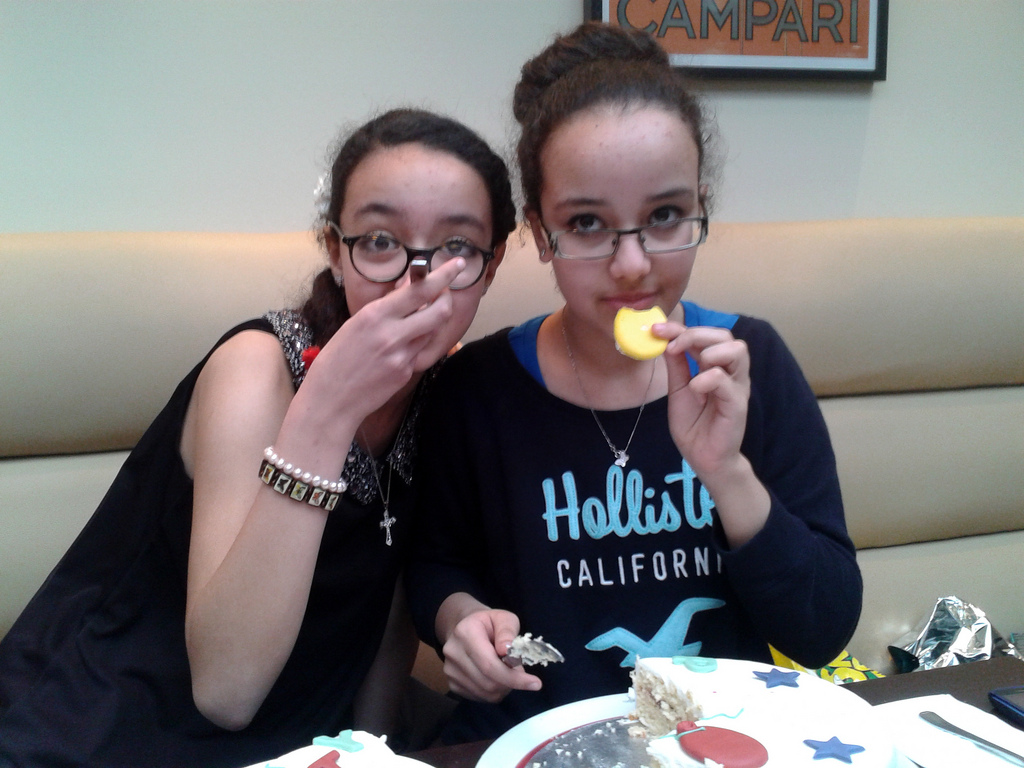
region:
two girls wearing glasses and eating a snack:
[0, 17, 868, 767]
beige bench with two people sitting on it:
[4, 19, 1023, 766]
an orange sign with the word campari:
[578, 1, 892, 79]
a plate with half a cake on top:
[460, 652, 890, 767]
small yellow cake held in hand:
[612, 306, 758, 474]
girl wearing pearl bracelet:
[4, 104, 521, 767]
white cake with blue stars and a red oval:
[622, 654, 891, 766]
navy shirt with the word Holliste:
[397, 311, 863, 745]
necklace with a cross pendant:
[355, 421, 401, 545]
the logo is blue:
[566, 579, 740, 687]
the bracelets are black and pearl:
[248, 424, 359, 529]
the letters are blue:
[529, 450, 732, 572]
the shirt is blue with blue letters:
[386, 330, 874, 703]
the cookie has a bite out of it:
[601, 292, 690, 365]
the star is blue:
[741, 632, 814, 709]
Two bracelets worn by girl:
[252, 437, 366, 524]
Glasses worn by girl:
[520, 182, 721, 263]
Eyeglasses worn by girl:
[337, 225, 505, 301]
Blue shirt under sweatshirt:
[484, 296, 748, 421]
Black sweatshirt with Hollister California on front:
[362, 286, 872, 758]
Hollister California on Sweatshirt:
[525, 444, 737, 596]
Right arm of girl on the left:
[171, 248, 470, 723]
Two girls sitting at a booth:
[0, 17, 890, 764]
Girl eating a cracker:
[400, 9, 866, 709]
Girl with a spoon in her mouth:
[8, 101, 520, 763]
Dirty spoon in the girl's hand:
[439, 581, 564, 714]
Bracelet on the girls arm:
[259, 442, 343, 519]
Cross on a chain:
[375, 493, 398, 554]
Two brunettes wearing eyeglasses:
[0, 23, 863, 764]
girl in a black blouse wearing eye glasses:
[0, 111, 514, 745]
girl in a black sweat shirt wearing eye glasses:
[517, 31, 860, 668]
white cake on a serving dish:
[477, 658, 908, 766]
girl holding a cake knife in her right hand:
[366, 401, 645, 765]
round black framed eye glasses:
[321, 217, 506, 297]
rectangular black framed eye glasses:
[520, 195, 716, 268]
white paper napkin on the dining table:
[875, 689, 1022, 763]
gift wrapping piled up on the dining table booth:
[815, 593, 1022, 683]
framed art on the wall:
[688, 0, 892, 93]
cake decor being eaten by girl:
[605, 295, 670, 368]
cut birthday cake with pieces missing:
[488, 654, 888, 763]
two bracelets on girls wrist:
[253, 446, 356, 507]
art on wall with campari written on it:
[596, 7, 898, 81]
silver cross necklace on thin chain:
[342, 443, 412, 555]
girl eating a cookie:
[398, 31, 968, 715]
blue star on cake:
[796, 724, 853, 766]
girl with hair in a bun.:
[411, 18, 880, 693]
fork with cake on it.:
[485, 618, 563, 676]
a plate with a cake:
[457, 647, 904, 766]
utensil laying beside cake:
[919, 691, 1019, 767]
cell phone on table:
[986, 682, 1022, 724]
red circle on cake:
[650, 711, 768, 766]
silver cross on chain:
[348, 426, 416, 560]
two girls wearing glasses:
[22, 13, 883, 715]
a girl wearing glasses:
[374, 113, 485, 338]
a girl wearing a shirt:
[541, 168, 859, 718]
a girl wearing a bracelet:
[239, 361, 411, 641]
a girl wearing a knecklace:
[482, 317, 698, 513]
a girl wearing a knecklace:
[315, 373, 481, 589]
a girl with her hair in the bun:
[459, 1, 675, 150]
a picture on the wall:
[798, 25, 923, 77]